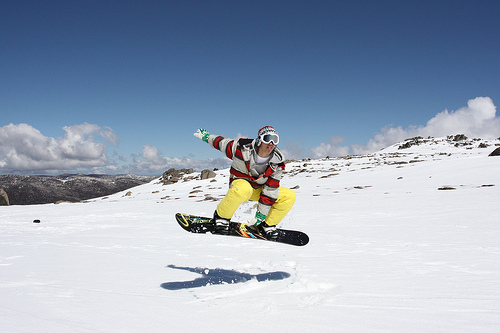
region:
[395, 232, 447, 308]
The snow is white.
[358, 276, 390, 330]
The snow is white.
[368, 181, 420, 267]
The snow is white.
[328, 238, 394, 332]
The snow is white.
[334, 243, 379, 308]
The snow is white.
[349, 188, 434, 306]
The snow is white.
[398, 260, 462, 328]
The snow is white.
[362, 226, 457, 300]
The snow is white.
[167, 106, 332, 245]
a snowboarder flying through the air.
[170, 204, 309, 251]
a black snow board.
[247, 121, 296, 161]
goggles on a face.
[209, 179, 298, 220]
bright yellow pants.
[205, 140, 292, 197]
red and white stripe shirt.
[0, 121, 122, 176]
a large gray cloud.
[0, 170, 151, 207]
a large mountain range.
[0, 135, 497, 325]
a snow covered ski slope.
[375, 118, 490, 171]
rocks on a hill top.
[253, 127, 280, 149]
a hipster.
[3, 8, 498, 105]
Blue sky without clouds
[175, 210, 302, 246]
Snowboard in air above snow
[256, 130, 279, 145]
Goggles on face of man snowboarding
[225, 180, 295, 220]
Man wearing yellow pants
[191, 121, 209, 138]
Green glove in air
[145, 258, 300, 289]
Shadow on snow ground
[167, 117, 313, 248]
Man snowboarding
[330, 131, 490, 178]
Rocky landscape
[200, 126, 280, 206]
Man wearing red coat and hat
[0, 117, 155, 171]
Clouds on blue sky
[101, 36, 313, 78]
Sky is blue color.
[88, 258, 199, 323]
Ground is white color.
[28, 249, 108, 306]
Snow in ground.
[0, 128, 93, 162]
Clouds are white color.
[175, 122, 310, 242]
One man is snowboarding.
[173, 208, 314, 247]
Snowboard is black color.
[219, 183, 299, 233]
Man is wearing yellow pant.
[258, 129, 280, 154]
Man is wearing goggles.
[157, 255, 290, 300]
Shadow falls on ground.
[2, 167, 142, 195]
Foot hill is seen behind the man.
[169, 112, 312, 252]
an airborne snowboarder on a clear day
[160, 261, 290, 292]
the shadow of a snowboarder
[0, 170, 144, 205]
mountains in a distance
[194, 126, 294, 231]
snowboarder in yellow pants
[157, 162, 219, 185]
rocks on the hill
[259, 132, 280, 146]
goggles on snowboarder's head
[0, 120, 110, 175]
clouds in the distance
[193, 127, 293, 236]
snowboarder with striped sweater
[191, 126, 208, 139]
glove on a snowboarder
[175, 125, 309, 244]
man holding snowboard with left hand